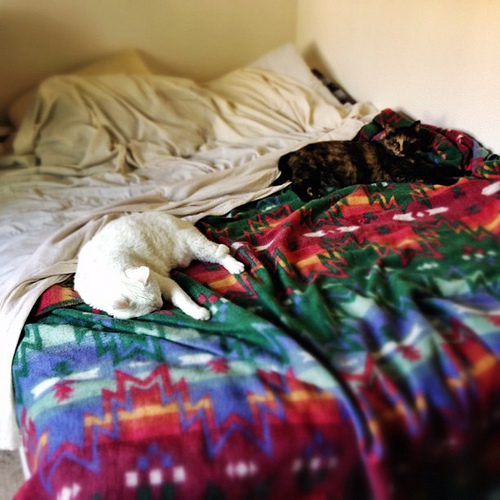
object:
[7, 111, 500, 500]
blanket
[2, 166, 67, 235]
white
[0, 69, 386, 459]
sheets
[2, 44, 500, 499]
bed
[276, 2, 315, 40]
corner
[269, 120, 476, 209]
cat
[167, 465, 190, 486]
blocks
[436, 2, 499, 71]
cream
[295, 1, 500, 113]
walls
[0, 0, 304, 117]
wall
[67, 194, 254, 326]
cats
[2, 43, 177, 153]
pillow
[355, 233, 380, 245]
pink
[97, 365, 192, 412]
stripe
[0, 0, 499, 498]
photo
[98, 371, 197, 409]
red and blue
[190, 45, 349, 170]
pillows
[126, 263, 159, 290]
cat ears